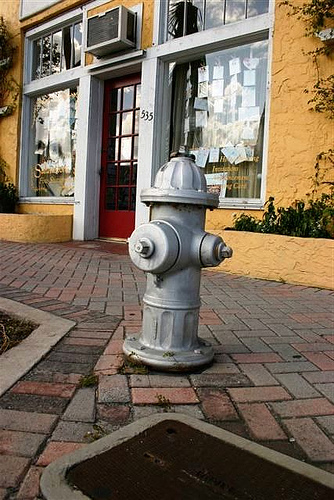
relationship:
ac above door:
[85, 6, 138, 58] [102, 73, 142, 238]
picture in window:
[237, 106, 262, 123] [203, 37, 268, 200]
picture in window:
[206, 148, 218, 163] [203, 37, 268, 200]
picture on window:
[197, 66, 209, 98] [203, 37, 268, 200]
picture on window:
[192, 111, 209, 125] [203, 37, 268, 200]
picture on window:
[243, 69, 256, 86] [203, 37, 268, 200]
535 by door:
[139, 106, 156, 125] [102, 73, 142, 238]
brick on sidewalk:
[281, 416, 334, 462] [2, 244, 113, 299]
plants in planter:
[225, 188, 333, 238] [234, 235, 332, 290]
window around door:
[26, 95, 77, 200] [102, 73, 142, 238]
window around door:
[28, 20, 83, 89] [102, 73, 142, 238]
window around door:
[157, 1, 269, 44] [102, 73, 142, 238]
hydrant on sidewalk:
[120, 146, 234, 374] [2, 244, 113, 299]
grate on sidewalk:
[67, 420, 333, 499] [2, 244, 113, 299]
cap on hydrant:
[127, 221, 177, 273] [120, 146, 234, 374]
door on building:
[102, 73, 142, 238] [273, 6, 304, 201]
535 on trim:
[139, 106, 156, 125] [74, 70, 98, 244]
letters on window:
[212, 154, 260, 189] [203, 37, 268, 200]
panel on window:
[205, 1, 225, 29] [157, 1, 269, 44]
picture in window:
[192, 111, 209, 125] [203, 37, 268, 200]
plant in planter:
[1, 183, 15, 213] [1, 214, 72, 246]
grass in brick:
[152, 392, 172, 409] [281, 416, 334, 462]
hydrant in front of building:
[120, 146, 234, 374] [273, 6, 304, 201]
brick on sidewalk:
[227, 383, 292, 403] [2, 244, 113, 299]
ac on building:
[85, 6, 138, 58] [273, 6, 304, 201]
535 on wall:
[139, 106, 156, 125] [142, 1, 157, 53]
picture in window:
[210, 78, 223, 99] [203, 37, 268, 200]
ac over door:
[85, 6, 138, 58] [102, 73, 142, 238]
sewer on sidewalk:
[65, 417, 332, 500] [2, 244, 113, 299]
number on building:
[139, 106, 156, 125] [273, 6, 304, 201]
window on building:
[26, 95, 77, 200] [273, 6, 304, 201]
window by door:
[203, 37, 268, 200] [102, 73, 142, 238]